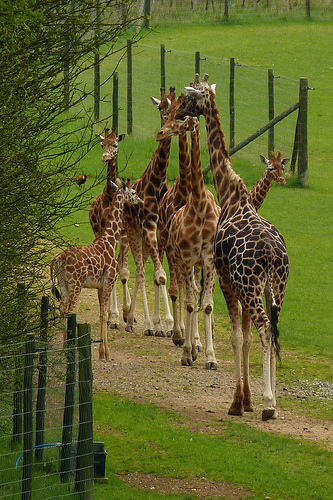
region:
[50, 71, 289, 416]
six giraffes standing in grass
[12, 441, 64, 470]
a blue hose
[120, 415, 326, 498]
green grass and brown dirt on the ground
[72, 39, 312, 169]
a wood and wire fence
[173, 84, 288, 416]
a giraffe standing up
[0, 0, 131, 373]
a tree off to the side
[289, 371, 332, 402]
rocks on the ground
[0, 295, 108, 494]
a wood and wire fence that is curved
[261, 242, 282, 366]
the tail of the giraffe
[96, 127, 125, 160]
a head of the giraffe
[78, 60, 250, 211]
a group of giraffes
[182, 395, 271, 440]
the grass is dead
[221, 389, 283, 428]
the giraffe has brown hooves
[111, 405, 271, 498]
the grass is next to the rocks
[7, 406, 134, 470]
a fence is by the trees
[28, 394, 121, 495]
the fence is made of metal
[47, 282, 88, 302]
the giraffe's tail is black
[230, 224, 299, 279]
the giraffe is black and tan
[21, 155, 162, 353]
trees are by the giraffe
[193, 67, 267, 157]
poles are by the fence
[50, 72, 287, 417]
A group of giraffes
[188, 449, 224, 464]
Part of the green grass.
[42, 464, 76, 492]
Part of a fence.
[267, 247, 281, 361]
The giraffe's long tail.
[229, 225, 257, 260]
Brown spots on the giraffe.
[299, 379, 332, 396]
A pile of rocks.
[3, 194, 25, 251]
Part of a tree.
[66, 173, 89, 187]
A small brown bird.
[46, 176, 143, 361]
A small giraffe.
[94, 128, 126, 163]
The head of the giraffe.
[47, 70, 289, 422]
a tower of giraffes standing on a path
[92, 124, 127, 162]
the head of a giraffe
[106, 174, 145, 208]
the head of a giraffe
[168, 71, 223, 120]
the head of a giraffe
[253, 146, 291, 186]
the head of a giraffe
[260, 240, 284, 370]
the tail of a giraffe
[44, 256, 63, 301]
the tail of a giraffe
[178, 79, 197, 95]
an ear of a giraffe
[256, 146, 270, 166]
an ear of a giraffe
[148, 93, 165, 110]
an ear of a giraffe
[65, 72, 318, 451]
group of giraffes on ground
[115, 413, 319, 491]
grass area on ground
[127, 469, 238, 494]
patch of ground without grass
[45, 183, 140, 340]
smallest giraffe in group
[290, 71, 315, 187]
wooden post on enclosure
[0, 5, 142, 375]
tree on side near giraffes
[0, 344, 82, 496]
fence area next to giraffes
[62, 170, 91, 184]
bird on the tree branch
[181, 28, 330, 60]
green area further from giraffe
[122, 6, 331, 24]
fence further away from giraffes